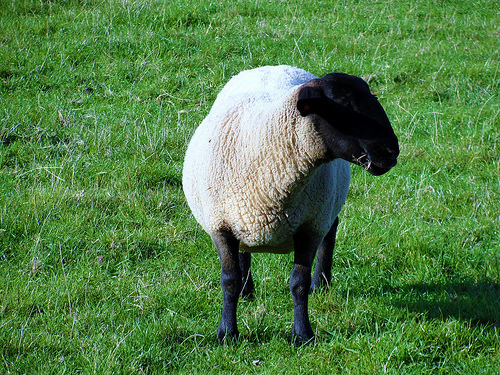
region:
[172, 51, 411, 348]
sheep with black head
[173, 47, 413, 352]
sheep with black legs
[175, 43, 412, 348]
sheep with tan body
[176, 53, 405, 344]
sheep's head faces right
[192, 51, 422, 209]
sheep eats mouthful of grass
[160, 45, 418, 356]
sheep stands on green grass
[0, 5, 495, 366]
sheep's hair looks recently shorn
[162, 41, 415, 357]
sheep stands on four legs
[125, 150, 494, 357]
shadow of sheep on grass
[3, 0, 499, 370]
weather is bright and sunny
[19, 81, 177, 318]
The grass is growing.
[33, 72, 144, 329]
The grass is lush.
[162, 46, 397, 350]
The sheep is standing.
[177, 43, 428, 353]
The sheep is white.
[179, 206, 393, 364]
The sheep has black legs.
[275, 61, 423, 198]
The sheep has a black head.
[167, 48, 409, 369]
The sheep is looking.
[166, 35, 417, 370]
Sheep have wool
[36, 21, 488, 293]
The sheep is in a field.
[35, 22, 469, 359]
The sheep is standing still.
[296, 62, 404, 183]
the head of a sheep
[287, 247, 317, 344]
the leg of a sheep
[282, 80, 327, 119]
the ear of a sheep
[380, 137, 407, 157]
the nose of a sheep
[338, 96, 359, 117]
the eye of a sheep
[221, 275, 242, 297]
the knee of a sheep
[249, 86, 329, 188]
the neck of a sheep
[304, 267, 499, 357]
a shadow on the ground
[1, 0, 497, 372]
a grassy green field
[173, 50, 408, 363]
a sheep on the grass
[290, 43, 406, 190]
sheep's head is black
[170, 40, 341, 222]
sheep's body is white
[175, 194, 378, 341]
sheep's legs are black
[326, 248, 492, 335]
shadow of sheep on grass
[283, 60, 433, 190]
sheep's head turned right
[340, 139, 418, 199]
grass in sheep's mouth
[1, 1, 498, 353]
sun shining on sheep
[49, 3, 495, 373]
sheep is by itself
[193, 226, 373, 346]
sheep has 4 legs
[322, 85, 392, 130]
sheep's eye is black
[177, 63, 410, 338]
a white sheep standing in a field.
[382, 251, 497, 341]
a shadow cast by a sheep.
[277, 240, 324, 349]
the front left leg.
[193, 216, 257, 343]
the right front leg.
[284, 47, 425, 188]
the head of a sheep.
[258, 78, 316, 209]
the neck of a sheep.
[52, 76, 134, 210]
a section of green grass.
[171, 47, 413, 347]
a sheep looking to the left.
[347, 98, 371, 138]
the right eye of a sheep.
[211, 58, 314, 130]
the back of a sheep.